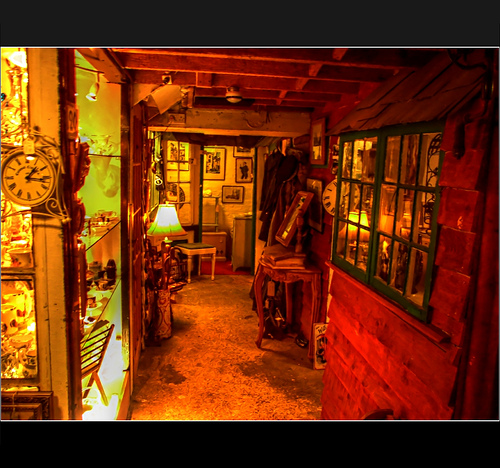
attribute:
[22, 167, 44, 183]
black hands —  black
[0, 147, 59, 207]
clock —  white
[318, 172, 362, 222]
round clock —   analog ,  round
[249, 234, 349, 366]
table —  fancy,  for end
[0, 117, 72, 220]
clock —   analog 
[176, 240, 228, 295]
stool —  green covered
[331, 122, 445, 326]
green frame —  green,  window's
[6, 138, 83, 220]
clock —  white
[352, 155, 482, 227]
panes —  green,  framed,  for window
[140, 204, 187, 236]
shade —  lamp's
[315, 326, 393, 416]
wall —  wooden,  panels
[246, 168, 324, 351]
stand —  small,  with stuff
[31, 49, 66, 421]
frame — for door,  white 